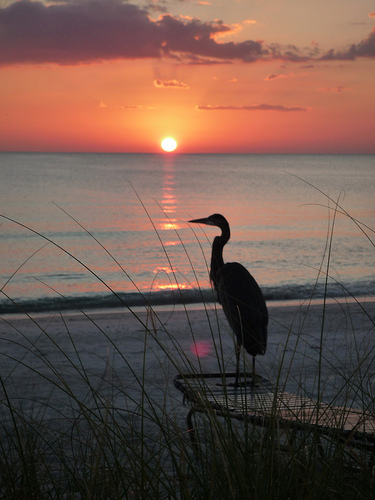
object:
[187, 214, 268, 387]
bird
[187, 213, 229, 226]
head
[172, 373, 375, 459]
chair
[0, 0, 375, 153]
sky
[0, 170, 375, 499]
grass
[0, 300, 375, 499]
beach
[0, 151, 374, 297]
water